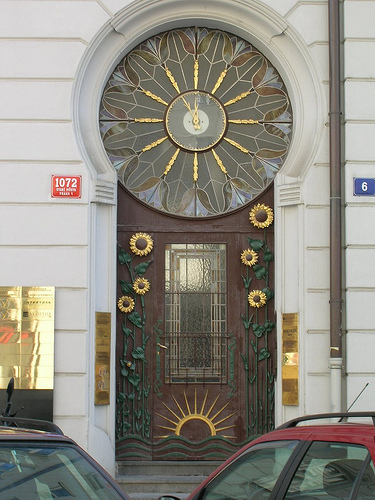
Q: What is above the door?
A: The large round window.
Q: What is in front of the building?
A: The red car.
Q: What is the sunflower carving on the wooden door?
A: Decorative.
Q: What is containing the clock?
A: The large round stained glass window.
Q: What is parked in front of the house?
A: The red car.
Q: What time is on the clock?
A: 11:55.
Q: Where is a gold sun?
A: Bottom of door.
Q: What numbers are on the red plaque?
A: 1072.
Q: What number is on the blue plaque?
A: 6.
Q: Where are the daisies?
A: Each side of door.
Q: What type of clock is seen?
A: Gold and silver ornately decorated.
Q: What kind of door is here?
A: Brown with glass window.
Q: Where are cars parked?
A: In front of the door.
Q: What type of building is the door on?
A: White stone.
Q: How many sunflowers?
A: Six.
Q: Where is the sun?
A: Bottom of door.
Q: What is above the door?
A: Clock.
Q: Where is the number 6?
A: On building.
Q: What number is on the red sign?
A: 1072.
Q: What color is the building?
A: White.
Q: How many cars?
A: Two.